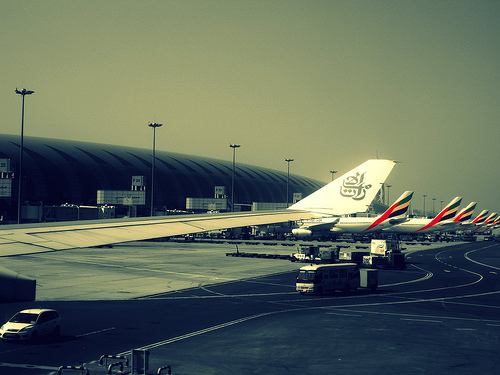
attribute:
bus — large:
[291, 260, 366, 300]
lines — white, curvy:
[426, 249, 500, 310]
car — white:
[3, 306, 69, 341]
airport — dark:
[4, 124, 320, 222]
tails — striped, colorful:
[380, 190, 499, 242]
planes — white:
[322, 185, 498, 239]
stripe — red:
[424, 209, 445, 230]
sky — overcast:
[8, 12, 478, 124]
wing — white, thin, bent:
[7, 198, 319, 256]